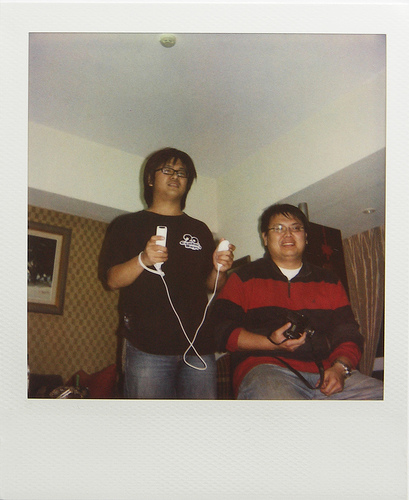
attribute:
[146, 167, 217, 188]
eyeglasses — black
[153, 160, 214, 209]
face — mans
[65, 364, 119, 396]
pillow — couch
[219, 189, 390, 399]
man — sitting down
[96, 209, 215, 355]
shirt — blue, black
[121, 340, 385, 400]
jeans — blue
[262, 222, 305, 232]
glasses — eye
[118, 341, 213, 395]
jeans — blue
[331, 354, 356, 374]
watch — wrist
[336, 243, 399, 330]
curtains — shiny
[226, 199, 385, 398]
man — young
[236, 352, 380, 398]
pants — blue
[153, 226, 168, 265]
game controller —  white 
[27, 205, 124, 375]
wall paper — gold, checkered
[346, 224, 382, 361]
curtains — window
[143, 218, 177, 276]
remote — wii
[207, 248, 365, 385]
shirt — black, red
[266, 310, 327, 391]
camera — black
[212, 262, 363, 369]
rugby shirt — red, black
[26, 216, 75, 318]
picture — framed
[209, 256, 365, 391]
shirt — red, black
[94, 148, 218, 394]
boy — young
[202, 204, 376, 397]
boy — young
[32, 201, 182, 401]
wall — living room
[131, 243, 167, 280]
strap — wii, wrist, remote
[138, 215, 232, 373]
controller — game